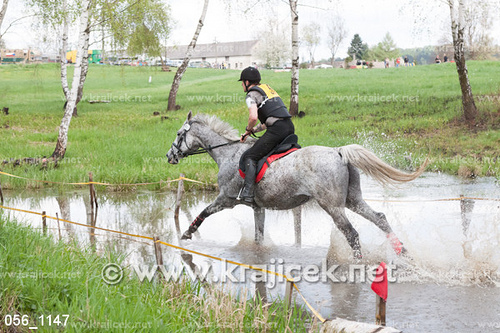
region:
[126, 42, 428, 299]
a jockey riding a horse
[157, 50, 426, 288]
a jockey riding a white horse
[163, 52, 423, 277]
a jockey riding a horse in the water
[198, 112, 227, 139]
the crest of the horse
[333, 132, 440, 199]
a tail of a horse with a splash of water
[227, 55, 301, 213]
a jockey wearing a black boots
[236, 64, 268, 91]
a jockey wearing a black hat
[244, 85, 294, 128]
a jockey wearing a black best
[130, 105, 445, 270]
a horse in motion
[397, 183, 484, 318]
splashing water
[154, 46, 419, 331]
the horse is wet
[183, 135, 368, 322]
the horse is wet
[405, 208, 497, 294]
big splash of water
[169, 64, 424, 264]
man riding a horse on water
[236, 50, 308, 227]
jockey on top of horse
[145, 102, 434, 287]
horse running in shallow water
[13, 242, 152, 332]
green grassy area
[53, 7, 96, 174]
tree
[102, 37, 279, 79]
barracks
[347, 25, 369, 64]
large pine tree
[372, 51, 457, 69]
spectators watching race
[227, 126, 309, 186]
black saddle with red cover on horse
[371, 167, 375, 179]
tail of a horse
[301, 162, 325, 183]
back of a horse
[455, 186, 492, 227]
part of a swamp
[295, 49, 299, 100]
stem of a tree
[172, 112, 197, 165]
head of a horse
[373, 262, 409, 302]
part of a swamp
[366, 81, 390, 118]
part of a grass plantation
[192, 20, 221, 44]
roof of a house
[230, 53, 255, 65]
edge of a building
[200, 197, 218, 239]
leg of a horse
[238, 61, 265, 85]
Man wearing black helmet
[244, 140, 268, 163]
Man wearing black pants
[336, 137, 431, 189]
Horse has grey tail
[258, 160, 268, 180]
Horse has red harnest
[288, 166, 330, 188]
Horse has grey fur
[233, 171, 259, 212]
Man has black boots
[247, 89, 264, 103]
Man wearing grey shirt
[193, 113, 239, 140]
Horse has greyish white mane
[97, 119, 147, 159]
Green grass in field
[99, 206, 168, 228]
Branch reflection in water